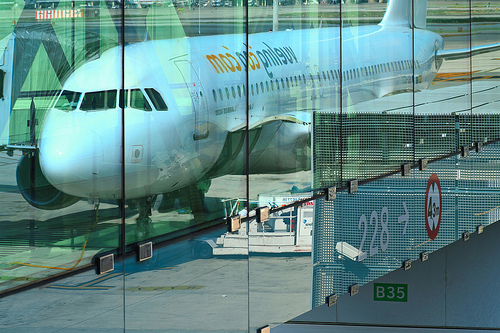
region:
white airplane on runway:
[60, 0, 489, 192]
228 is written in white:
[355, 174, 415, 270]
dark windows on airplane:
[63, 78, 158, 133]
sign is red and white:
[414, 163, 462, 249]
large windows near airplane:
[100, 2, 258, 234]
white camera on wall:
[338, 234, 369, 278]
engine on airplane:
[30, 131, 69, 216]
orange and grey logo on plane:
[191, 27, 302, 99]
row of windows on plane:
[203, 51, 448, 128]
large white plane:
[69, 0, 434, 178]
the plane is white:
[32, 10, 402, 289]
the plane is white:
[71, 41, 310, 200]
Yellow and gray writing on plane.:
[197, 40, 324, 84]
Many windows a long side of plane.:
[211, 71, 413, 98]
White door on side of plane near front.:
[168, 43, 221, 155]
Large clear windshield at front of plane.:
[53, 79, 199, 136]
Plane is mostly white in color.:
[88, 51, 370, 130]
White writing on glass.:
[348, 196, 424, 268]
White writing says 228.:
[330, 197, 430, 254]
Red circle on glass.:
[413, 155, 455, 257]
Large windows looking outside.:
[27, 89, 464, 278]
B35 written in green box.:
[367, 274, 425, 321]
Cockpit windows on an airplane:
[46, 63, 165, 125]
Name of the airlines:
[202, 43, 307, 83]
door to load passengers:
[156, 62, 238, 147]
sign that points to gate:
[347, 206, 424, 275]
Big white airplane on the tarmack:
[22, 21, 487, 218]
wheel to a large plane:
[124, 196, 215, 244]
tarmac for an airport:
[68, 286, 246, 329]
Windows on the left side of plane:
[208, 82, 255, 102]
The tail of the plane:
[363, 1, 439, 23]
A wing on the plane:
[435, 40, 498, 67]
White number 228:
[355, 200, 393, 250]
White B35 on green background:
[370, 281, 407, 299]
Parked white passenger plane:
[33, 5, 494, 240]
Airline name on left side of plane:
[198, 41, 310, 76]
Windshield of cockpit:
[40, 80, 170, 115]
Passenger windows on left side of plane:
[195, 55, 430, 102]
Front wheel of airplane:
[128, 208, 156, 244]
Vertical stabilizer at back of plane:
[376, 0, 434, 30]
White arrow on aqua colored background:
[388, 195, 413, 238]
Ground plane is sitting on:
[5, 173, 261, 284]